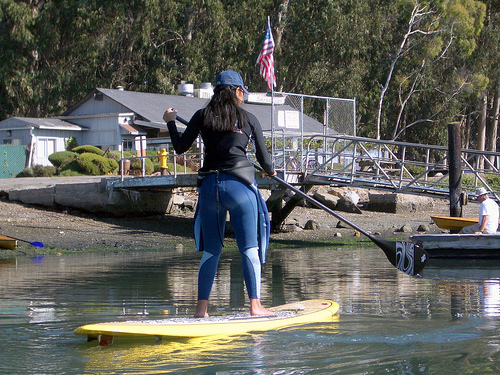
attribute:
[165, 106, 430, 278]
stick — black 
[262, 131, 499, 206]
bridge — small 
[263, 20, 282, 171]
flag pole — silver 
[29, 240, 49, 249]
oar — blue 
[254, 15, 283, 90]
flag — large , American 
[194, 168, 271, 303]
wetsuit — blue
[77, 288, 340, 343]
paddle — black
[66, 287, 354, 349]
paddle board — yellow 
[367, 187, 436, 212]
boulder — large 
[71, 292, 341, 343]
paddle board — yellow 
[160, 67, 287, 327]
woman — barefoot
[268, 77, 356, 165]
fence — large 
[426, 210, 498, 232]
boat — yellow 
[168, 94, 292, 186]
shirt — black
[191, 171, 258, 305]
pants — blue, swimwear